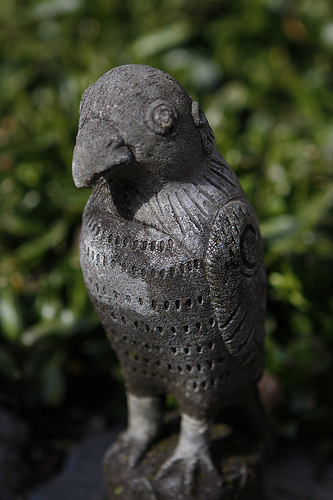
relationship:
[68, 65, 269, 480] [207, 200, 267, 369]
statue has wing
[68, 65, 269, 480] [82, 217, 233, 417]
statue has breast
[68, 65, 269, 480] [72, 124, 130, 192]
statue has beak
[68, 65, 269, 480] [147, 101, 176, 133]
statue has eye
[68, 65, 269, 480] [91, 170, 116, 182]
statue has nostril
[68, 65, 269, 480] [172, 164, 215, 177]
statue has neck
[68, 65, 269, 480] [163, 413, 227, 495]
statue has foot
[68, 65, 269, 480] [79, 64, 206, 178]
statue has head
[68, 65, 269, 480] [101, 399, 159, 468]
statue has foot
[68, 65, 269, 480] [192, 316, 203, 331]
statue has hole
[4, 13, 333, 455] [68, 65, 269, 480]
leaves behind statue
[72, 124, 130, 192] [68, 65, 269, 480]
beak of statue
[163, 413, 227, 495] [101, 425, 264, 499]
foot on pedestool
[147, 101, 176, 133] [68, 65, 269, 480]
eye of statue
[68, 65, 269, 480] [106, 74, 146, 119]
statue made of stone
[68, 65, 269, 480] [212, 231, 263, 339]
statue has etching